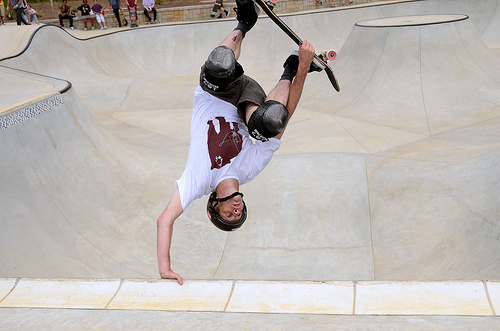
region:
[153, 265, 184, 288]
right hand grabbing concrete tiled kerb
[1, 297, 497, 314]
edge of concrete tiles is yellowing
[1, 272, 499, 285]
most grabbed edge of tiles turning brown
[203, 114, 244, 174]
upside down brown bear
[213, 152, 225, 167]
white muzzle on screenprinted brown bear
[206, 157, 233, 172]
ears end in dull points on screenprinted brown bear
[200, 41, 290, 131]
grey dusty kneepads of skater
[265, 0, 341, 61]
orangey red rimmed white wheels of skateboard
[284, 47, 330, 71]
black skate sneaker has white rubber sole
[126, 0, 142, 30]
person in burgundy shirt holds skateboard wheels-out in background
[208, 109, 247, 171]
bear image on the shirt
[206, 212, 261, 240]
the helmet is black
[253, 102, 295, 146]
the kneepads are black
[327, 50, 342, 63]
the wheels are red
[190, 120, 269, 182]
the shirt is white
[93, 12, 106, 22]
the pants are white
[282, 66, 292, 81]
the socks are black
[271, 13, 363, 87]
the skateboard is made of wood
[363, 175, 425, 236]
the skate board is made of concrete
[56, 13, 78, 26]
the pants are black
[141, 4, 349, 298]
Skater upside down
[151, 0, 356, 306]
Skater up side down and supporting with right hand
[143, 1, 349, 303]
Skater wearing white shirt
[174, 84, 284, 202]
White shirt is printed with a brown bear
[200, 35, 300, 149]
Knee pads are black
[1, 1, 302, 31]
People in the background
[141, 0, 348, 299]
Skater wearing helmet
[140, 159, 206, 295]
Right hand on border of skate trail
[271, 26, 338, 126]
Right hand holding the skateboard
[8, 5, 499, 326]
Skate trail is white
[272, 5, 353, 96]
skateboarder doing tricks on skateboard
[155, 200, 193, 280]
skater using arm while skateboarding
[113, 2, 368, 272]
boy skating at skate park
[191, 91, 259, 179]
brown bear on t-shirt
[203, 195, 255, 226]
helmet being worn by skateboarder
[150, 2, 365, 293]
upside down skateboarder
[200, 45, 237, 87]
knee pads on skater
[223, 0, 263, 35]
black shoes on skater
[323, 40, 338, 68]
skateboard wheels on skateboard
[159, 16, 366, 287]
skateboarder doing tricks at skate park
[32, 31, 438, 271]
it is in a skatepark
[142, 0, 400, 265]
the boy is skating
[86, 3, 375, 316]
it is a daytime scene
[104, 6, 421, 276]
it is an outdoor scene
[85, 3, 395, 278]
the boy is using a skateboard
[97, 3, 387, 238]
the boy has a white shirt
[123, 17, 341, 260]
the boy has a helmet on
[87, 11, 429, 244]
the boy has guards on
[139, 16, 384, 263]
the board is in air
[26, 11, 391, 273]
the boy is supporting himself using his hand